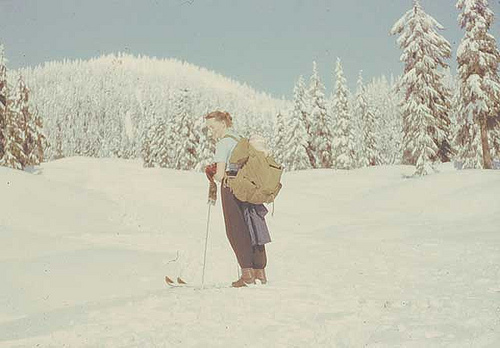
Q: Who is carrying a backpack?
A: The woman.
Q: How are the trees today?
A: Snow covered.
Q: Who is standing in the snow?
A: The woman.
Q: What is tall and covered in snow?
A: The mountains.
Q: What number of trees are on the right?
A: Two.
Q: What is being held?
A: Ski poles.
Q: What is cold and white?
A: Snow.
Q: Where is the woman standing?
A: In the snow.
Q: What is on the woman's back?
A: A brown bag.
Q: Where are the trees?
A: Behind the woman.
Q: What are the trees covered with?
A: Snow.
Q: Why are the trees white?
A: Snow covered.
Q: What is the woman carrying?
A: A backpack.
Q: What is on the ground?
A: Snow.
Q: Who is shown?
A: A woman.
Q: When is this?
A: During the day.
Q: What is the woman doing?
A: Skiing.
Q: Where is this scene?
A: The mountains.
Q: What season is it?
A: Winter.